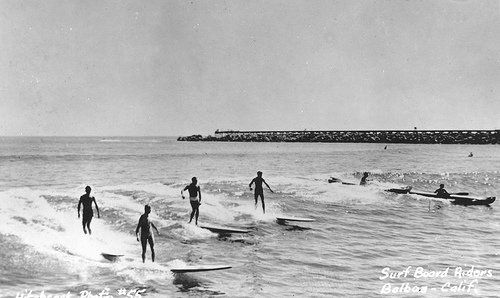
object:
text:
[379, 266, 496, 281]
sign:
[378, 266, 493, 294]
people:
[78, 186, 99, 235]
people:
[249, 171, 274, 214]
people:
[359, 172, 368, 187]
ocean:
[0, 128, 499, 297]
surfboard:
[384, 184, 413, 194]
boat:
[327, 176, 496, 206]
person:
[135, 205, 160, 264]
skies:
[81, 20, 396, 94]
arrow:
[20, 175, 116, 263]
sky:
[2, 2, 498, 119]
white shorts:
[189, 196, 199, 201]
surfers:
[78, 170, 275, 264]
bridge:
[177, 128, 500, 144]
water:
[8, 132, 497, 274]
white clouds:
[251, 46, 353, 96]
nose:
[8, 176, 68, 274]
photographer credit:
[377, 266, 493, 296]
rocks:
[176, 126, 495, 142]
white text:
[379, 265, 497, 296]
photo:
[0, 0, 498, 296]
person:
[77, 185, 100, 235]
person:
[179, 175, 202, 225]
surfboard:
[277, 214, 316, 222]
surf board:
[200, 224, 249, 234]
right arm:
[181, 185, 190, 197]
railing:
[210, 127, 500, 134]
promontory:
[175, 129, 500, 144]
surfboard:
[99, 253, 233, 273]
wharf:
[180, 127, 499, 142]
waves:
[5, 168, 311, 294]